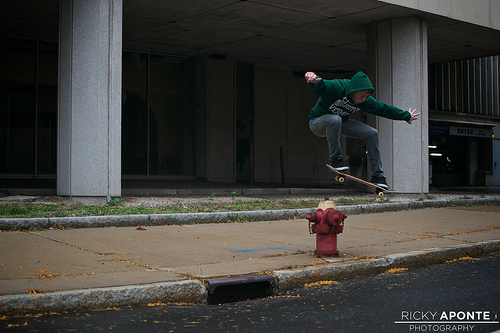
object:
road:
[316, 305, 343, 322]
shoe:
[328, 152, 351, 172]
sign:
[451, 122, 495, 138]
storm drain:
[207, 275, 279, 306]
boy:
[304, 70, 422, 190]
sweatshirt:
[310, 70, 412, 122]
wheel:
[337, 176, 345, 181]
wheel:
[376, 191, 388, 196]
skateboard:
[324, 157, 398, 196]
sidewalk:
[11, 210, 268, 272]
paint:
[227, 243, 298, 254]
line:
[213, 251, 302, 264]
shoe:
[370, 180, 389, 189]